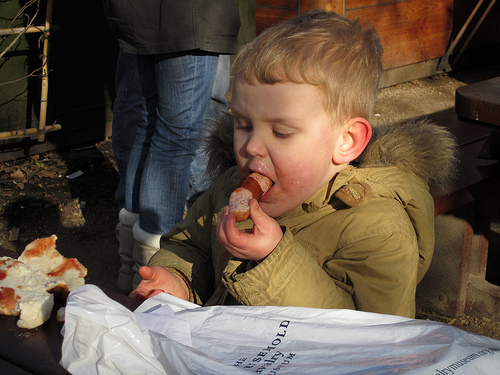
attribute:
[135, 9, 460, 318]
young boy — young 